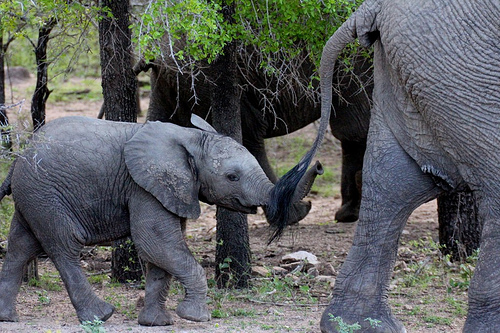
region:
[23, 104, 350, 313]
a small gray elephant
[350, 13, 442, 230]
elephant's skin is wrinkled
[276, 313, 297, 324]
this is the ground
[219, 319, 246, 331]
the ground is sandy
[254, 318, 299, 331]
the sand is brown in color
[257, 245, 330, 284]
these are some rocks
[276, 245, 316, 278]
the rocks are small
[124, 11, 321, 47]
these are some branches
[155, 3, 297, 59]
the branches have leaves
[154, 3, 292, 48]
the leaves are green in color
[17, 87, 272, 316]
this is a calf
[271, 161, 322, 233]
Long hair on end of tail.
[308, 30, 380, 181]
Elephant has long gray tail.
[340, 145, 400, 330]
Elephant has wrinkly gray leg.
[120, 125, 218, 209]
Elephant has large gray ear.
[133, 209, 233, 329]
Elephant has gray wrinkly leg.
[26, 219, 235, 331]
Elephant is walking in dirt.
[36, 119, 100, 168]
Elephant has gray back.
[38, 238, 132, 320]
Elephant has gray back leg.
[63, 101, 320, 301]
Elephant walking in front of trees.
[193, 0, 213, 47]
Green leaves on trees.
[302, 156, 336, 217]
Elephant trunk underneath elephant hair.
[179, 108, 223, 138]
Elephant trunk underneath elephant hair.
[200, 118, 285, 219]
Baby elephant trunk underneath another elephant.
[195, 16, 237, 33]
Baby elephant trunk underneath another elephant.